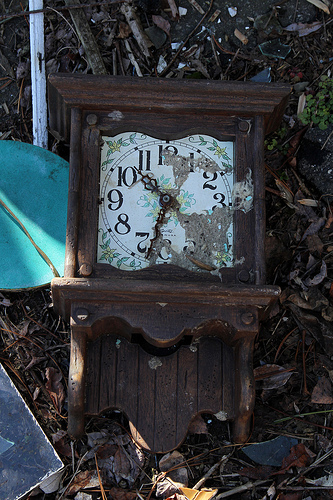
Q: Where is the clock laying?
A: On the ground.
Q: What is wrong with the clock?
A: It's broken.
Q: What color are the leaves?
A: Brown.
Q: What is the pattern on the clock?
A: Floral.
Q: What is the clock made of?
A: Wood.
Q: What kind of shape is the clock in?
A: Worn and tires.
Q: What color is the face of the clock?
A: White.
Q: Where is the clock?
A: Forest.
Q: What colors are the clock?
A: Brown and white.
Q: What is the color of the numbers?
A: Black.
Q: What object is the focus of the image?
A: A clock.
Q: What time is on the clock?
A: 10:33.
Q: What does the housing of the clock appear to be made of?
A: Wood.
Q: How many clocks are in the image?
A: One.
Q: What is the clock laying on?
A: The ground.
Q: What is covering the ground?
A: Sticks and leaves.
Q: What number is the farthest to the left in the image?
A: 9.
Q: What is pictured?
A: A clock.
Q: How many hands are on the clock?
A: Two.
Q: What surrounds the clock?
A: Wood.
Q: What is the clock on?
A: A wooden stand.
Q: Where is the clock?
A: On the ground.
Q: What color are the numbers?
A: Black.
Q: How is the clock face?
A: Dirty.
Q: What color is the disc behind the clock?
A: Blue.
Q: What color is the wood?
A: Brown.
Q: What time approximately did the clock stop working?
A: 10:33.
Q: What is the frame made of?
A: Wood.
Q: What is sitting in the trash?
A: An old clock.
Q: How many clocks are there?
A: One.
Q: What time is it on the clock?
A: 10:33.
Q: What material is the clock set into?
A: Wood.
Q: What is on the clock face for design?
A: A floral pattern.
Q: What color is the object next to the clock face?
A: Green.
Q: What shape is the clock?
A: Square.